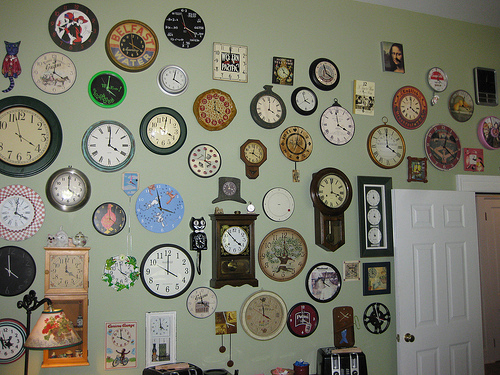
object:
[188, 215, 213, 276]
clock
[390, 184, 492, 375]
door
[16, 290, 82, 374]
lamp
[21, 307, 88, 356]
shade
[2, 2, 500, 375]
wall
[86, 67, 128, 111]
clock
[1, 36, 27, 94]
cat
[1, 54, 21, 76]
shirt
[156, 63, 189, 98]
clock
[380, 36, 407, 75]
picture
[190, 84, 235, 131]
clock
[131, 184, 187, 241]
clock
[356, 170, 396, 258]
clocks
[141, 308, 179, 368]
clocks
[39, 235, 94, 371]
clocks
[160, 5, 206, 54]
clock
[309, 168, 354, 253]
clock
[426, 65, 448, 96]
clock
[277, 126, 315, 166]
clock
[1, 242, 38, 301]
clock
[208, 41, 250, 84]
clock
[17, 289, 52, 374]
stand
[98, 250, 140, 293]
clock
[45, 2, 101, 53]
clock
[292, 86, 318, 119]
clock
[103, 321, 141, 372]
clock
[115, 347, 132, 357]
curious george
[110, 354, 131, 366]
bicycle